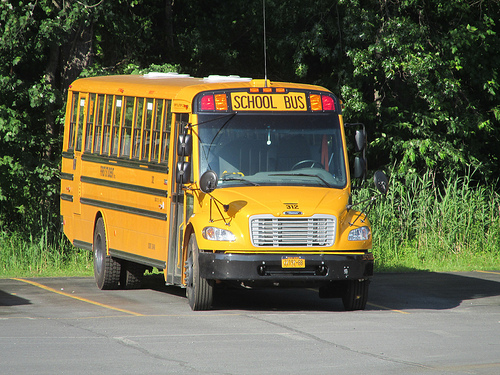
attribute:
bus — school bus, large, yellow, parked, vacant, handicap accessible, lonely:
[58, 70, 374, 312]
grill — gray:
[252, 214, 338, 246]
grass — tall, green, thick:
[3, 157, 499, 277]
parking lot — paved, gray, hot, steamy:
[4, 269, 499, 375]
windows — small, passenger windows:
[69, 91, 169, 167]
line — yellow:
[9, 271, 155, 320]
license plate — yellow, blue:
[279, 257, 309, 270]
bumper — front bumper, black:
[202, 254, 366, 284]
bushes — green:
[3, 2, 499, 232]